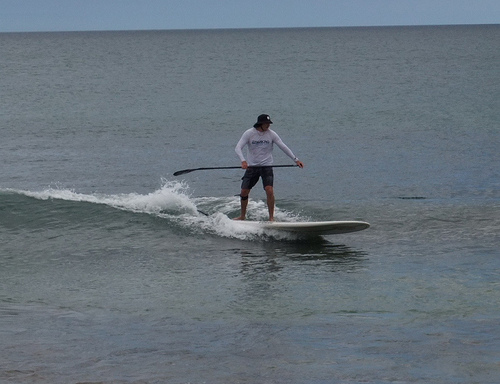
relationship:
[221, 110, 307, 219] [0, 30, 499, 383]
person on water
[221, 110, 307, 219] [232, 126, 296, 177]
person wearing shirt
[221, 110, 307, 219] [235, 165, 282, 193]
person wearing shorts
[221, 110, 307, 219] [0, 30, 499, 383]
person in water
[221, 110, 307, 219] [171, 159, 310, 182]
person has oar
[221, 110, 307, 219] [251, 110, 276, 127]
person wearing hat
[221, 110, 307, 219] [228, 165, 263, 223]
person has leg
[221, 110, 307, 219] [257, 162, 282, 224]
person has leg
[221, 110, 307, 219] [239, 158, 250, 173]
person has hand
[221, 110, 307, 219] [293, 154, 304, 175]
person has hand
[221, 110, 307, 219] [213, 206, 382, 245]
person riding paddleboard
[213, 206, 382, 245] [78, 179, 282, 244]
paddleboard riding wave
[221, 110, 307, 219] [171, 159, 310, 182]
person holding oar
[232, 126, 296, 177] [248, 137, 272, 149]
shirt has word